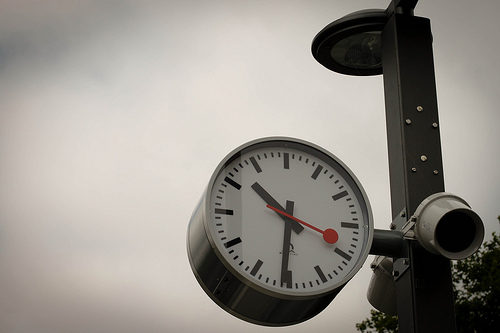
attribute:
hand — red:
[264, 200, 347, 248]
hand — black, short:
[250, 178, 305, 235]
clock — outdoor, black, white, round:
[179, 131, 377, 333]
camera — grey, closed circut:
[408, 185, 490, 265]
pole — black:
[377, 0, 458, 333]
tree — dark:
[359, 231, 499, 326]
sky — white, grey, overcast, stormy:
[5, 4, 305, 130]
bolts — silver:
[403, 99, 444, 182]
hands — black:
[249, 175, 307, 286]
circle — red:
[318, 223, 342, 247]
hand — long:
[276, 196, 299, 285]